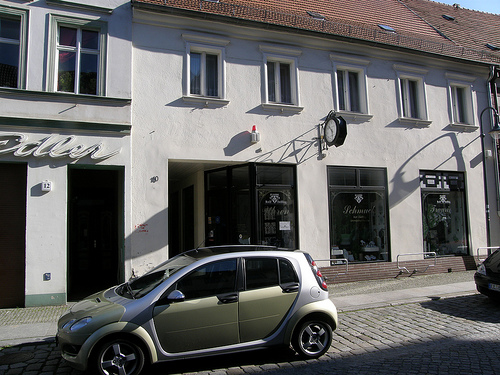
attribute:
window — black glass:
[420, 190, 470, 255]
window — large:
[319, 154, 396, 265]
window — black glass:
[42, 18, 109, 103]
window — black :
[338, 69, 359, 111]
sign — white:
[277, 217, 292, 230]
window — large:
[420, 169, 470, 258]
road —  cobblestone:
[6, 298, 497, 370]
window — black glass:
[328, 165, 393, 263]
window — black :
[398, 74, 429, 114]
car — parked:
[474, 239, 499, 299]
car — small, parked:
[55, 243, 340, 373]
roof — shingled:
[153, 1, 498, 62]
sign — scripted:
[10, 117, 115, 174]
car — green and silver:
[62, 244, 352, 365]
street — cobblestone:
[323, 298, 483, 361]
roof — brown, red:
[132, 0, 498, 66]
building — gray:
[104, 3, 498, 245]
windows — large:
[320, 159, 398, 265]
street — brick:
[331, 292, 489, 358]